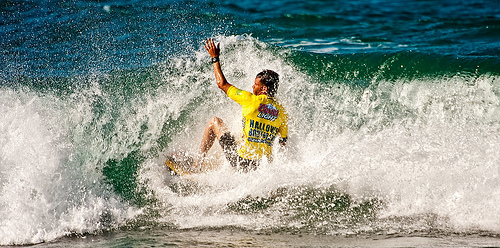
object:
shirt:
[225, 84, 295, 174]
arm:
[211, 57, 238, 104]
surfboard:
[164, 149, 244, 192]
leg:
[199, 116, 233, 161]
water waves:
[1, 35, 499, 241]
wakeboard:
[158, 115, 326, 203]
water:
[342, 54, 457, 210]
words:
[244, 115, 282, 144]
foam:
[370, 72, 481, 192]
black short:
[218, 133, 260, 173]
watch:
[211, 57, 219, 63]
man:
[185, 36, 290, 176]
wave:
[0, 28, 499, 246]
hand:
[203, 38, 220, 56]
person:
[183, 31, 315, 212]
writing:
[248, 103, 280, 146]